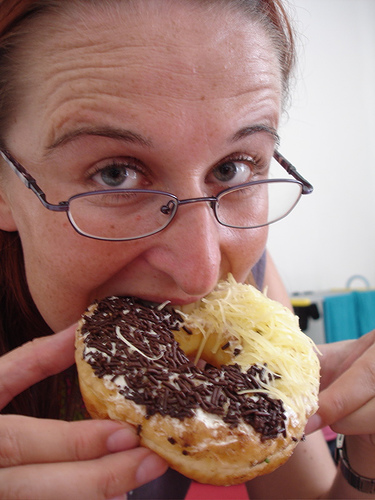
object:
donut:
[74, 275, 321, 487]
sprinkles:
[102, 323, 172, 385]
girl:
[0, 1, 375, 500]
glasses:
[43, 182, 310, 240]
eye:
[84, 158, 152, 193]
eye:
[209, 150, 260, 190]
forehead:
[39, 9, 280, 116]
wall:
[293, 1, 374, 168]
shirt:
[187, 479, 250, 498]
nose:
[145, 176, 222, 299]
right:
[195, 1, 373, 482]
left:
[1, 2, 197, 500]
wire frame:
[2, 148, 66, 212]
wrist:
[346, 435, 375, 478]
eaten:
[118, 291, 238, 314]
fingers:
[2, 452, 168, 499]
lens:
[70, 191, 171, 237]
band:
[335, 434, 374, 499]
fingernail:
[110, 425, 139, 448]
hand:
[298, 330, 374, 445]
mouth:
[113, 284, 234, 307]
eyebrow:
[37, 122, 152, 151]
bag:
[324, 278, 375, 340]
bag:
[293, 294, 320, 332]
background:
[279, 205, 374, 341]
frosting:
[234, 306, 294, 355]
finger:
[0, 413, 141, 468]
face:
[39, 1, 270, 330]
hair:
[242, 1, 299, 90]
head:
[0, 2, 295, 346]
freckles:
[178, 219, 201, 231]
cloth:
[253, 248, 266, 288]